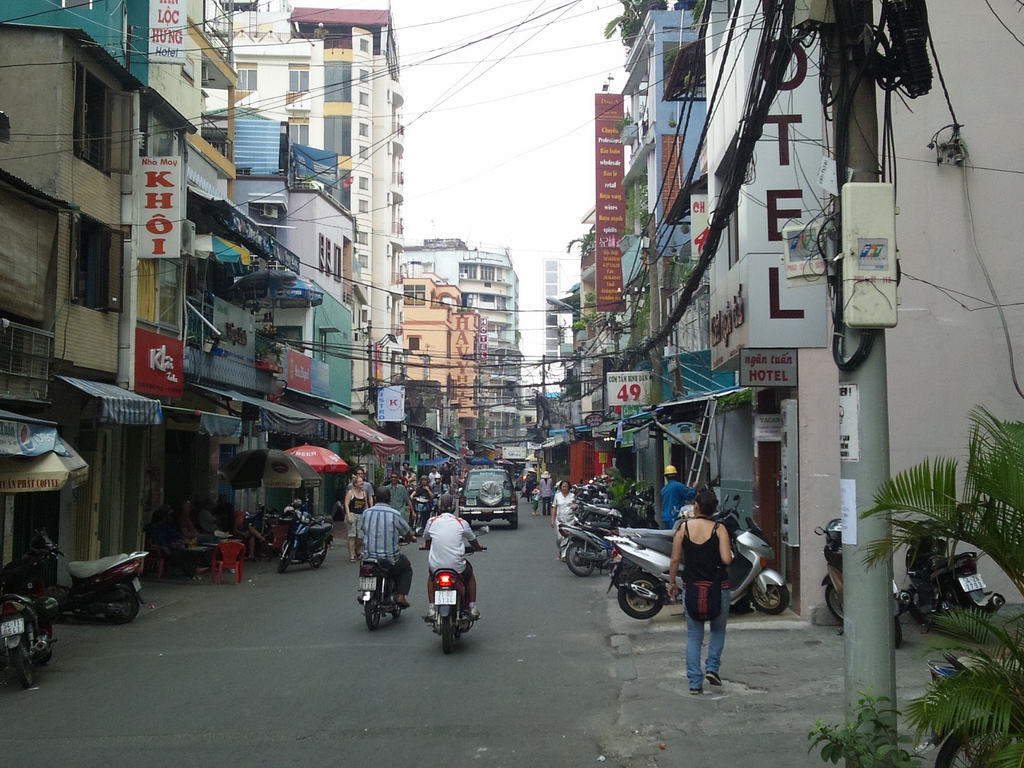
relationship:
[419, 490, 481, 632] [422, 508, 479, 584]
man wearing shirt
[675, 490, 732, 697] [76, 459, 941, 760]
woman walking on side of road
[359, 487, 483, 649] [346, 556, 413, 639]
man on motorcycle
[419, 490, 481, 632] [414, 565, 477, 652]
man on motorcycle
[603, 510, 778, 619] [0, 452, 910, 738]
motorcycle parked on side of road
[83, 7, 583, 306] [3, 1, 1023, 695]
cables hanging between buildings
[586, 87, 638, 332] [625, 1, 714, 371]
sign on building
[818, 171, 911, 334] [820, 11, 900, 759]
box on pole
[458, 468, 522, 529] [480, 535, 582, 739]
car in middle of road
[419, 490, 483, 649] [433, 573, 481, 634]
man riding motorcycle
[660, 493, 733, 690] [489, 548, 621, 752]
lady walking beside street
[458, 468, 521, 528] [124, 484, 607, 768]
car in road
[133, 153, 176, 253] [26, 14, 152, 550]
sign attached building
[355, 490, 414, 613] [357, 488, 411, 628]
man riding motorcycle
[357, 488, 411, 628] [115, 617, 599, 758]
motorcycle in street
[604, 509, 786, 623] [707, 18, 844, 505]
motorcycle in front of building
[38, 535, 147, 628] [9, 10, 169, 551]
motorcycle in front of building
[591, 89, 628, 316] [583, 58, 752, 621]
sign attached to building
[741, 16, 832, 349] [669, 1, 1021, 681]
sign on side of building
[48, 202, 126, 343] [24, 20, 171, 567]
window on building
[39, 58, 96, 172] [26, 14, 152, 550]
window on building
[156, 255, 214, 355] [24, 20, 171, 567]
window on building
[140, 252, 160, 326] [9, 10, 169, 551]
window on building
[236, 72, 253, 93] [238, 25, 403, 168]
window on building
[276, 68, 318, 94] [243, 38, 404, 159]
window on building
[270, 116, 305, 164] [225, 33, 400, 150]
window on building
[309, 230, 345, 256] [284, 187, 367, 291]
window on building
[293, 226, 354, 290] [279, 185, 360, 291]
window on building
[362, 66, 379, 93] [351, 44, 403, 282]
window on building